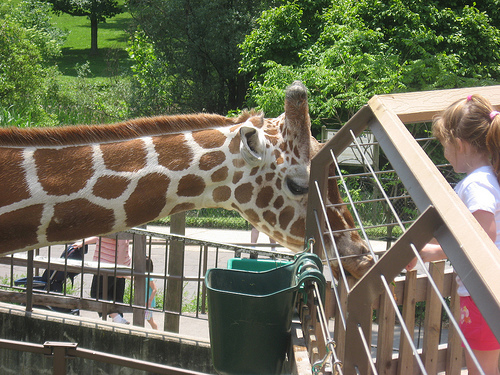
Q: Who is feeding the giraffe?
A: A girl.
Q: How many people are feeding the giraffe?
A: One.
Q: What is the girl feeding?
A: A giraffe.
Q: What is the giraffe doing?
A: Eating.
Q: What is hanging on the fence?
A: Buckets.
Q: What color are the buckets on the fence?
A: Green.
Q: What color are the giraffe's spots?
A: Brown.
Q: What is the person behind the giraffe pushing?
A: A stroller.